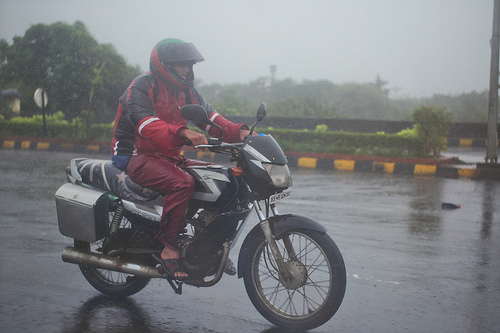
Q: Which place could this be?
A: It is a road.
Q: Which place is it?
A: It is a road.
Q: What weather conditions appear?
A: It is overcast.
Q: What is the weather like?
A: It is overcast.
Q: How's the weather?
A: It is overcast.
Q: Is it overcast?
A: Yes, it is overcast.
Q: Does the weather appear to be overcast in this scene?
A: Yes, it is overcast.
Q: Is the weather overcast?
A: Yes, it is overcast.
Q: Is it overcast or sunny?
A: It is overcast.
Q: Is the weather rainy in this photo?
A: No, it is overcast.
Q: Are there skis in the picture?
A: No, there are no skis.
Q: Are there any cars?
A: No, there are no cars.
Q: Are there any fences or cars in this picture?
A: No, there are no cars or fences.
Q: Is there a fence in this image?
A: No, there are no fences.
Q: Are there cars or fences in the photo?
A: No, there are no fences or cars.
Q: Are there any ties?
A: No, there are no ties.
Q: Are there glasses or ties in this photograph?
A: No, there are no ties or glasses.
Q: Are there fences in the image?
A: No, there are no fences.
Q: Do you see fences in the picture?
A: No, there are no fences.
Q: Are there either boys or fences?
A: No, there are no fences or boys.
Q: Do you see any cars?
A: No, there are no cars.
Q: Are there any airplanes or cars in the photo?
A: No, there are no cars or airplanes.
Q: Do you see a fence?
A: No, there are no fences.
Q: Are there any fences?
A: No, there are no fences.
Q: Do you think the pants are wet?
A: Yes, the pants are wet.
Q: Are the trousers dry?
A: No, the trousers are wet.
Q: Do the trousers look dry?
A: No, the trousers are wet.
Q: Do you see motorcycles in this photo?
A: Yes, there is a motorcycle.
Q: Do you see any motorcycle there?
A: Yes, there is a motorcycle.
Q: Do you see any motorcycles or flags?
A: Yes, there is a motorcycle.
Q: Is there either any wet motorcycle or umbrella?
A: Yes, there is a wet motorcycle.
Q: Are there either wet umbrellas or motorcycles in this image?
A: Yes, there is a wet motorcycle.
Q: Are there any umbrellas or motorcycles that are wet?
A: Yes, the motorcycle is wet.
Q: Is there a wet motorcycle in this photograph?
A: Yes, there is a wet motorcycle.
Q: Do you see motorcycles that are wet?
A: Yes, there is a motorcycle that is wet.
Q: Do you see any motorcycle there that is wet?
A: Yes, there is a motorcycle that is wet.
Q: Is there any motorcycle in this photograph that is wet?
A: Yes, there is a motorcycle that is wet.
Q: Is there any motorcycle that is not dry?
A: Yes, there is a wet motorcycle.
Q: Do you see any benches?
A: No, there are no benches.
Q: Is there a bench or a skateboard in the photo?
A: No, there are no benches or skateboards.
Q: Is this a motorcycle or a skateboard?
A: This is a motorcycle.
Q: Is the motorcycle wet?
A: Yes, the motorcycle is wet.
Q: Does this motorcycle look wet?
A: Yes, the motorcycle is wet.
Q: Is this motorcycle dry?
A: No, the motorcycle is wet.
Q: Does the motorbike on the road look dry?
A: No, the motorbike is wet.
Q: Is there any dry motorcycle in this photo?
A: No, there is a motorcycle but it is wet.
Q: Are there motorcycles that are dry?
A: No, there is a motorcycle but it is wet.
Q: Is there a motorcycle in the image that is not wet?
A: No, there is a motorcycle but it is wet.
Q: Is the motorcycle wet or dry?
A: The motorcycle is wet.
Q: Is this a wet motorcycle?
A: Yes, this is a wet motorcycle.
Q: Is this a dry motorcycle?
A: No, this is a wet motorcycle.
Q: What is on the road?
A: The motorbike is on the road.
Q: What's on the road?
A: The motorbike is on the road.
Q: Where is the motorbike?
A: The motorbike is on the road.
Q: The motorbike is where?
A: The motorbike is on the road.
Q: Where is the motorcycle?
A: The motorbike is on the road.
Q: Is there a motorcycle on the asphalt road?
A: Yes, there is a motorcycle on the road.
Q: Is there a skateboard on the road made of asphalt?
A: No, there is a motorcycle on the road.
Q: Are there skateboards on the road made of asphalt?
A: No, there is a motorcycle on the road.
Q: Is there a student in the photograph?
A: No, there are no students.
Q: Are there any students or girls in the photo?
A: No, there are no students or girls.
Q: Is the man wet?
A: Yes, the man is wet.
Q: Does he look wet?
A: Yes, the man is wet.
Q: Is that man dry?
A: No, the man is wet.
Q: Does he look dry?
A: No, the man is wet.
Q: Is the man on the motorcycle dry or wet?
A: The man is wet.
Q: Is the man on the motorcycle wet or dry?
A: The man is wet.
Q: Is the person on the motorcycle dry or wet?
A: The man is wet.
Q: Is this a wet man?
A: Yes, this is a wet man.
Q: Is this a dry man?
A: No, this is a wet man.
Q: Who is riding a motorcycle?
A: The man is riding a motorcycle.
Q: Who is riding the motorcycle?
A: The man is riding a motorcycle.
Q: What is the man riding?
A: The man is riding a motorcycle.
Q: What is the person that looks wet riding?
A: The man is riding a motorcycle.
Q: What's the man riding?
A: The man is riding a motorcycle.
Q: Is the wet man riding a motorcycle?
A: Yes, the man is riding a motorcycle.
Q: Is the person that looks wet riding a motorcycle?
A: Yes, the man is riding a motorcycle.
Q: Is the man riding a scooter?
A: No, the man is riding a motorcycle.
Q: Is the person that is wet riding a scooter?
A: No, the man is riding a motorcycle.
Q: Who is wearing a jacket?
A: The man is wearing a jacket.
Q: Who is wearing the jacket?
A: The man is wearing a jacket.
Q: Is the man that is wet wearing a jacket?
A: Yes, the man is wearing a jacket.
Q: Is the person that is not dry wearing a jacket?
A: Yes, the man is wearing a jacket.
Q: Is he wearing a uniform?
A: No, the man is wearing a jacket.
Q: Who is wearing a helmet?
A: The man is wearing a helmet.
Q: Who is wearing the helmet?
A: The man is wearing a helmet.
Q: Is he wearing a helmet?
A: Yes, the man is wearing a helmet.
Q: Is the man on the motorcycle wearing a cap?
A: No, the man is wearing a helmet.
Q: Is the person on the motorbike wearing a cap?
A: No, the man is wearing a helmet.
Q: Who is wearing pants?
A: The man is wearing pants.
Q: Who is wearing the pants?
A: The man is wearing pants.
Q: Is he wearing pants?
A: Yes, the man is wearing pants.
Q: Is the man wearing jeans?
A: No, the man is wearing pants.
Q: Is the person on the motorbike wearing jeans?
A: No, the man is wearing pants.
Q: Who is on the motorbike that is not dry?
A: The man is on the motorcycle.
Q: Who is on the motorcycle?
A: The man is on the motorcycle.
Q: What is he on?
A: The man is on the motorcycle.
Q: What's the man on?
A: The man is on the motorcycle.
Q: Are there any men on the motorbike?
A: Yes, there is a man on the motorbike.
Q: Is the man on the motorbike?
A: Yes, the man is on the motorbike.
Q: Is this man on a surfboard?
A: No, the man is on the motorbike.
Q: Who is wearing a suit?
A: The man is wearing a suit.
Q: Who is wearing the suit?
A: The man is wearing a suit.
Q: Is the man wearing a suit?
A: Yes, the man is wearing a suit.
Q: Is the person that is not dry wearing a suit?
A: Yes, the man is wearing a suit.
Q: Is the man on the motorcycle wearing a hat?
A: No, the man is wearing a suit.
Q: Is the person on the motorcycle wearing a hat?
A: No, the man is wearing a suit.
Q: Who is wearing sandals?
A: The man is wearing sandals.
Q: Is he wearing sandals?
A: Yes, the man is wearing sandals.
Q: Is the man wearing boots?
A: No, the man is wearing sandals.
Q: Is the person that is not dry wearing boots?
A: No, the man is wearing sandals.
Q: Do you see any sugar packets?
A: No, there are no sugar packets.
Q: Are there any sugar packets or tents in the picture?
A: No, there are no sugar packets or tents.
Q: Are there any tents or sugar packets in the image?
A: No, there are no sugar packets or tents.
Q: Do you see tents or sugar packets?
A: No, there are no sugar packets or tents.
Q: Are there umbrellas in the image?
A: No, there are no umbrellas.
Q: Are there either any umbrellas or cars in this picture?
A: No, there are no umbrellas or cars.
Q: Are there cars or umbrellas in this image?
A: No, there are no umbrellas or cars.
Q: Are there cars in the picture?
A: No, there are no cars.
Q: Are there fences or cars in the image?
A: No, there are no cars or fences.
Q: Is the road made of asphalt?
A: Yes, the road is made of asphalt.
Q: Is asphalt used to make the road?
A: Yes, the road is made of asphalt.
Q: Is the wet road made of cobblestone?
A: No, the road is made of asphalt.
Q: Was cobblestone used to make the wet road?
A: No, the road is made of asphalt.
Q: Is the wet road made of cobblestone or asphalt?
A: The road is made of asphalt.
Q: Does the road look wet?
A: Yes, the road is wet.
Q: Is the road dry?
A: No, the road is wet.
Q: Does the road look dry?
A: No, the road is wet.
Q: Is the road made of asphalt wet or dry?
A: The road is wet.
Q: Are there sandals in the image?
A: Yes, there are sandals.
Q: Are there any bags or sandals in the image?
A: Yes, there are sandals.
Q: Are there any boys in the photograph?
A: No, there are no boys.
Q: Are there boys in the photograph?
A: No, there are no boys.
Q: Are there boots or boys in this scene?
A: No, there are no boys or boots.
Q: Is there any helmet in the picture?
A: Yes, there is a helmet.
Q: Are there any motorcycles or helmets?
A: Yes, there is a helmet.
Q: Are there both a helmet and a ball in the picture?
A: No, there is a helmet but no balls.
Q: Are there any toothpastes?
A: No, there are no toothpastes.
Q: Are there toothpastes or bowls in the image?
A: No, there are no toothpastes or bowls.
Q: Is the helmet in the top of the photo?
A: Yes, the helmet is in the top of the image.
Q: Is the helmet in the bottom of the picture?
A: No, the helmet is in the top of the image.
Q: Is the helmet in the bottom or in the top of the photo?
A: The helmet is in the top of the image.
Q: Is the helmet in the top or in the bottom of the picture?
A: The helmet is in the top of the image.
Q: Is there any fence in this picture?
A: No, there are no fences.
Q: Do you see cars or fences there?
A: No, there are no fences or cars.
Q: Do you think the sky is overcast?
A: Yes, the sky is overcast.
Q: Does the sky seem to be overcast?
A: Yes, the sky is overcast.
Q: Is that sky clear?
A: No, the sky is overcast.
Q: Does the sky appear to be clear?
A: No, the sky is overcast.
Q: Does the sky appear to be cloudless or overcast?
A: The sky is overcast.